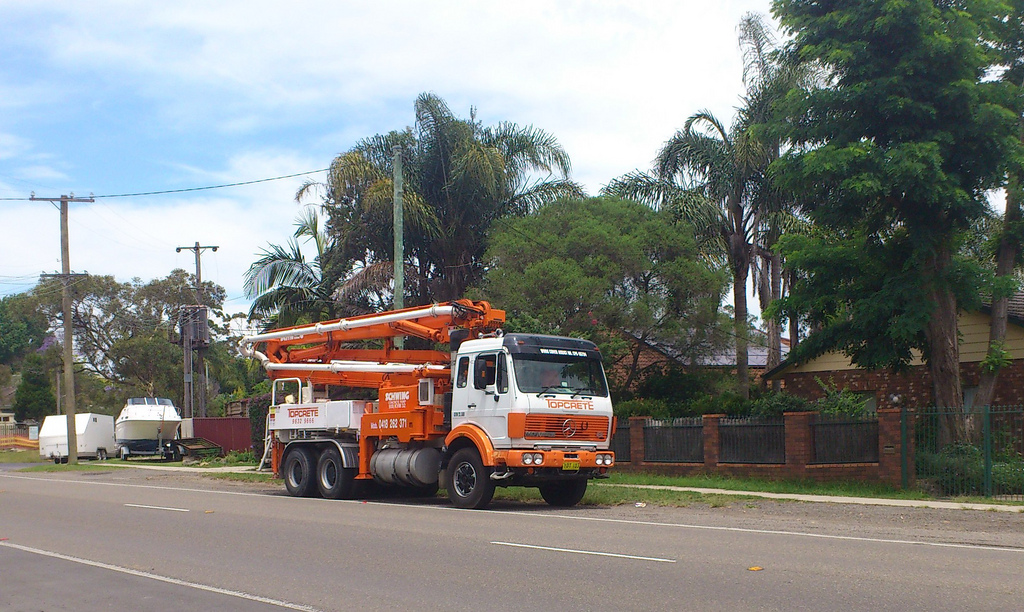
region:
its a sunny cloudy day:
[43, 27, 320, 165]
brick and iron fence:
[616, 398, 923, 485]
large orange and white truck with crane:
[245, 299, 626, 499]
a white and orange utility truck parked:
[250, 306, 620, 513]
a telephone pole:
[10, 183, 124, 471]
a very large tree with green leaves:
[712, 0, 1022, 476]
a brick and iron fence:
[630, 405, 932, 497]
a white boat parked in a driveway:
[115, 388, 211, 466]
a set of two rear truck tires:
[272, 443, 349, 502]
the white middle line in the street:
[108, 490, 204, 523]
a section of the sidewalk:
[695, 483, 961, 509]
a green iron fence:
[911, 404, 1020, 493]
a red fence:
[196, 414, 261, 447]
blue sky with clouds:
[4, 2, 780, 290]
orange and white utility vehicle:
[241, 300, 616, 504]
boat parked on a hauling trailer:
[108, 391, 192, 465]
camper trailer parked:
[35, 410, 124, 461]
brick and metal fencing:
[614, 409, 925, 495]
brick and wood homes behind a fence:
[598, 299, 1023, 402]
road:
[5, 458, 1015, 605]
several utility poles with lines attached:
[19, 178, 220, 472]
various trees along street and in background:
[5, 3, 1018, 412]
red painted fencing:
[184, 398, 268, 455]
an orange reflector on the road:
[743, 561, 767, 572]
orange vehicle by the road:
[247, 292, 622, 521]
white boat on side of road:
[117, 387, 190, 461]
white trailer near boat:
[40, 408, 120, 463]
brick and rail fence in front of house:
[625, 403, 924, 493]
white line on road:
[484, 526, 691, 574]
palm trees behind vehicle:
[242, 86, 559, 312]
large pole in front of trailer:
[16, 176, 99, 458]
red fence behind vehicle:
[186, 410, 257, 462]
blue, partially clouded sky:
[28, 17, 779, 221]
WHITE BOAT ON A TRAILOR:
[106, 392, 196, 476]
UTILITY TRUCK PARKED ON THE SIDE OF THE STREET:
[235, 291, 622, 535]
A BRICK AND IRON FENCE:
[624, 406, 913, 495]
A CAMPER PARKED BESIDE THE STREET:
[27, 390, 123, 480]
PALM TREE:
[640, 112, 811, 426]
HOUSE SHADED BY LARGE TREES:
[760, 213, 1018, 490]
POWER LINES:
[11, 185, 233, 402]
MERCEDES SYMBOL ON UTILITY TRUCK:
[529, 400, 605, 458]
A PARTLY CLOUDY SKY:
[49, 30, 331, 214]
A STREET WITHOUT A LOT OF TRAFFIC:
[20, 461, 381, 610]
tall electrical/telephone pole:
[40, 184, 95, 495]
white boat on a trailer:
[114, 393, 184, 485]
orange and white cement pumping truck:
[230, 306, 619, 497]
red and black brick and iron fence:
[625, 404, 914, 491]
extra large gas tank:
[363, 430, 446, 492]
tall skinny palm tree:
[664, 115, 766, 411]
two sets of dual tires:
[274, 440, 372, 499]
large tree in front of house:
[771, 7, 1013, 502]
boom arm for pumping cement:
[239, 294, 500, 372]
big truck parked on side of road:
[211, 306, 651, 518]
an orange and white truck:
[247, 287, 622, 506]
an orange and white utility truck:
[240, 295, 614, 510]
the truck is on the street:
[100, 156, 995, 558]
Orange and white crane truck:
[233, 310, 626, 545]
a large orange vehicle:
[242, 273, 620, 520]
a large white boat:
[105, 354, 200, 468]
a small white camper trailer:
[30, 392, 128, 476]